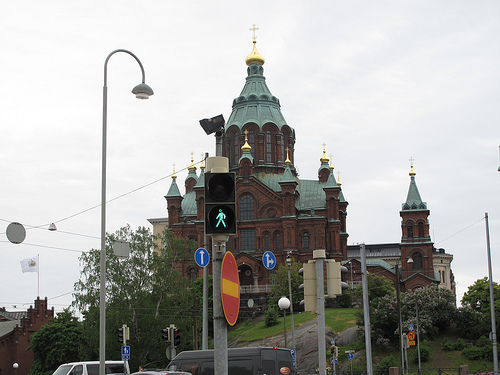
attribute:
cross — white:
[245, 23, 266, 43]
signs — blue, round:
[193, 249, 278, 271]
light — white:
[133, 89, 154, 104]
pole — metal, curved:
[91, 48, 117, 373]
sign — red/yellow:
[215, 251, 248, 332]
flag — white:
[15, 251, 41, 281]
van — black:
[167, 342, 299, 373]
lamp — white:
[277, 288, 293, 315]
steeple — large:
[245, 15, 273, 73]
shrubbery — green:
[365, 287, 498, 369]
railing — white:
[239, 284, 274, 294]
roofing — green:
[219, 71, 307, 128]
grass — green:
[327, 300, 360, 330]